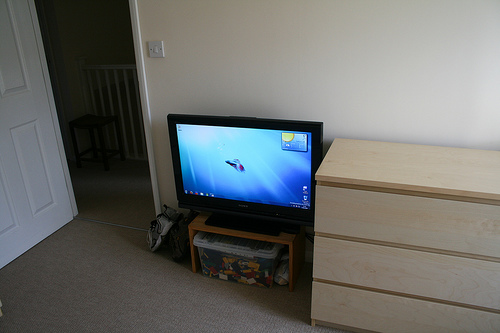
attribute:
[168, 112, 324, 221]
tv — black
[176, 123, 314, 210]
screen — flat, on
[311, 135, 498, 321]
dresser — tan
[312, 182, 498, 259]
drawer — large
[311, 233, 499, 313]
drawer — large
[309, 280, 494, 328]
drawer — large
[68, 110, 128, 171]
stool — little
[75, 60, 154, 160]
railing — white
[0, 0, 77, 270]
door — white, painted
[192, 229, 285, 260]
lid — white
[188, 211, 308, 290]
table — small, wooden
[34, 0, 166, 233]
doorway — dark